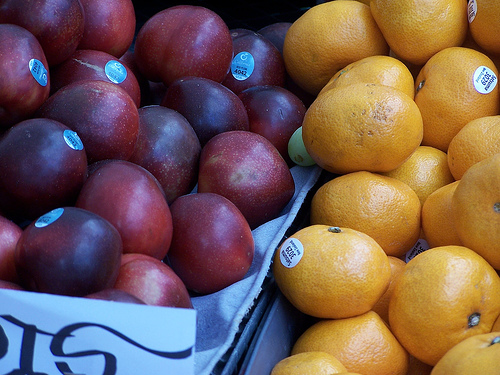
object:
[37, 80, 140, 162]
red plum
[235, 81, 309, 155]
fruit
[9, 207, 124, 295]
plum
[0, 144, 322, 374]
crate